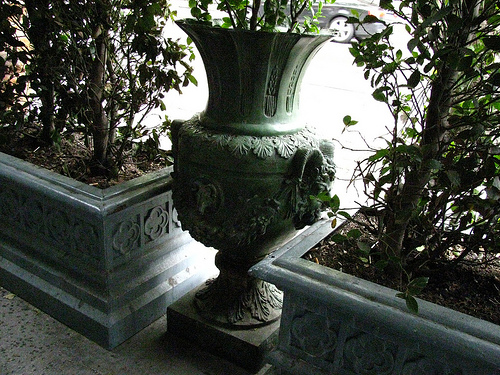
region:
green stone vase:
[174, 15, 329, 347]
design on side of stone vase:
[282, 150, 340, 235]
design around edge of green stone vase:
[178, 122, 320, 160]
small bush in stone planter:
[351, 0, 498, 266]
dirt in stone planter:
[447, 276, 497, 312]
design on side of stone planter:
[284, 295, 374, 372]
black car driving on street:
[290, 0, 391, 45]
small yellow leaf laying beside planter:
[0, 280, 22, 309]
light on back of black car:
[359, 5, 389, 22]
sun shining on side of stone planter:
[160, 233, 217, 285]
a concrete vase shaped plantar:
[171, 7, 350, 340]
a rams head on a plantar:
[189, 179, 221, 212]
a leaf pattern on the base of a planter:
[245, 282, 271, 322]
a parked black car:
[240, 1, 390, 46]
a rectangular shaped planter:
[0, 106, 237, 336]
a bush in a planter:
[345, 1, 495, 272]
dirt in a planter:
[443, 238, 497, 313]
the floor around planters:
[0, 285, 263, 373]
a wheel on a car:
[328, 13, 353, 41]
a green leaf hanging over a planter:
[390, 287, 421, 317]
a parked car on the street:
[233, 0, 390, 50]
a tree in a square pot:
[1, 2, 167, 298]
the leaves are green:
[282, 103, 471, 290]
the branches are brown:
[46, 17, 156, 146]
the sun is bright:
[301, 6, 398, 144]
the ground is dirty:
[0, 305, 92, 365]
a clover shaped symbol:
[92, 203, 145, 273]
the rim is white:
[323, 12, 361, 42]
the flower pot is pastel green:
[0, 170, 171, 346]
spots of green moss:
[19, 322, 54, 351]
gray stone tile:
[137, 345, 174, 374]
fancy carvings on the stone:
[186, 175, 257, 237]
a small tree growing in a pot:
[201, 2, 312, 28]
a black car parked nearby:
[326, 2, 388, 35]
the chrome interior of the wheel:
[337, 21, 349, 37]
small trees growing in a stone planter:
[10, 6, 131, 162]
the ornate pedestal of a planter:
[209, 257, 260, 329]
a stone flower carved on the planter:
[294, 315, 346, 367]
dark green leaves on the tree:
[401, 291, 419, 310]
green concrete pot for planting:
[172, 16, 330, 366]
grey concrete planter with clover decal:
[247, 191, 499, 370]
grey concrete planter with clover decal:
[17, 134, 225, 351]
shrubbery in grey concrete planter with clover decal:
[0, 0, 152, 174]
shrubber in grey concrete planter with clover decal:
[350, 0, 495, 265]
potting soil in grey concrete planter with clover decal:
[301, 203, 498, 322]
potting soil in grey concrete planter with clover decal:
[0, 121, 197, 189]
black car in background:
[217, 0, 392, 44]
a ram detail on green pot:
[185, 173, 225, 220]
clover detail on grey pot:
[288, 302, 338, 364]